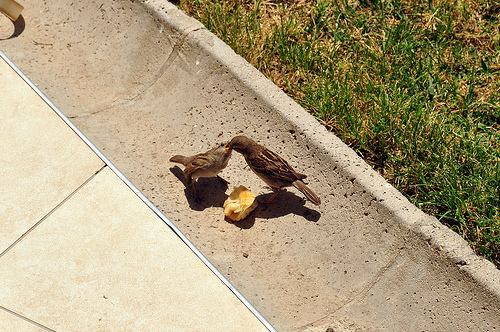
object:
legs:
[262, 183, 288, 202]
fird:
[226, 133, 324, 208]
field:
[168, 1, 500, 270]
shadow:
[164, 164, 231, 212]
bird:
[168, 140, 236, 207]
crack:
[0, 162, 114, 257]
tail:
[289, 178, 321, 208]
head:
[220, 140, 230, 156]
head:
[221, 135, 251, 152]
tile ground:
[0, 50, 271, 330]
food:
[225, 183, 263, 223]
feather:
[246, 155, 271, 176]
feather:
[295, 178, 324, 206]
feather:
[287, 171, 302, 182]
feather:
[264, 150, 289, 168]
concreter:
[0, 52, 106, 258]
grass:
[171, 0, 500, 265]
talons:
[259, 191, 284, 209]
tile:
[2, 166, 278, 331]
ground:
[0, 0, 500, 331]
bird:
[225, 134, 323, 206]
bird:
[117, 185, 221, 222]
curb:
[0, 0, 500, 329]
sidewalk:
[0, 0, 500, 331]